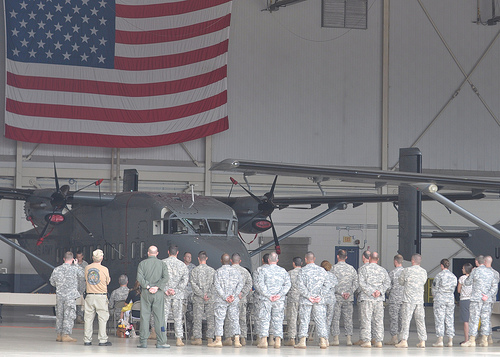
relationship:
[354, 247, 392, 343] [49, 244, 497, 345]
serviceman in line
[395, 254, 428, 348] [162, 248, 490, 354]
soldier in line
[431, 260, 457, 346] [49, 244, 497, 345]
serviceman in line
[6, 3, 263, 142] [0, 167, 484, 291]
american flag hanging over plane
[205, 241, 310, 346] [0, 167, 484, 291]
soldier standing in front of plane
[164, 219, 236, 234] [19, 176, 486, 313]
window on plane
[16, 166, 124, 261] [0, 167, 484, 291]
propellar on plane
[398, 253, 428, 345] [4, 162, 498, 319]
soldier in front of plane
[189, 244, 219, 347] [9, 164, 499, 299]
soldier in front of plane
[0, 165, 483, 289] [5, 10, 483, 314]
airplane in hangar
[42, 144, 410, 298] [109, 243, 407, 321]
plane in front of men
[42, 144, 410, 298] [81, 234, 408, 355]
plane in front of women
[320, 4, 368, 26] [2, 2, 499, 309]
window on building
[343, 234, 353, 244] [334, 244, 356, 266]
sign above door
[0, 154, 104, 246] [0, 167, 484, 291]
propellar on plane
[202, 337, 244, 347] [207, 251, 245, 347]
boots on man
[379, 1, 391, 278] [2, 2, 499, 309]
pole going up side of building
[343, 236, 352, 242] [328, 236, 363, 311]
sign above door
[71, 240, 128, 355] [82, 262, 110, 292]
person in shirt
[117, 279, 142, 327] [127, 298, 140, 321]
woman sitting on chair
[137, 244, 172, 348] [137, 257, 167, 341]
men in uniform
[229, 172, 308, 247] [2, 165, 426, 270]
propeller on plane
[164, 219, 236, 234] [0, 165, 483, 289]
window on airplane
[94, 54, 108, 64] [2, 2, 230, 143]
star on flag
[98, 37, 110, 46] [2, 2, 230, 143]
star on flag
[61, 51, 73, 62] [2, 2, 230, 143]
star on flag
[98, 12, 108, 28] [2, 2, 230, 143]
star on flag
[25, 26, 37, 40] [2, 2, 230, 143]
star on flag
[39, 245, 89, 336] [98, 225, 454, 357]
serviceman standing in a line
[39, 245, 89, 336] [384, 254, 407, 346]
serviceman standing in a soldiers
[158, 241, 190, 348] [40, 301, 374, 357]
serviceman standing in a line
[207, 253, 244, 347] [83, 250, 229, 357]
man standing in a line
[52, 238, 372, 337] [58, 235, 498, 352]
serviceman standing in a line